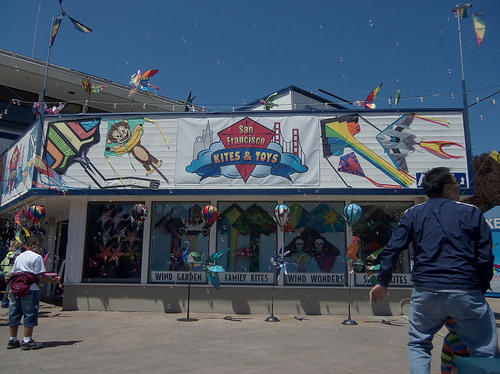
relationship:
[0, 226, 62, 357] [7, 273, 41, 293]
boy wearing fanny pack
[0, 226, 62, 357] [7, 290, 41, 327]
boy wearing jean shorts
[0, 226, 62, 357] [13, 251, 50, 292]
boy wearing shirt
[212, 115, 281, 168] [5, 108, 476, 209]
san francisco kites written on sign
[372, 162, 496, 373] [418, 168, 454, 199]
man has hair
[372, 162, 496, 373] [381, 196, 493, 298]
man wearing jacket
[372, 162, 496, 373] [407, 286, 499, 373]
man wearing jeans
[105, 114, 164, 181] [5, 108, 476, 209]
monkey on sign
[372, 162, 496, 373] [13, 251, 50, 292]
man wearing shirt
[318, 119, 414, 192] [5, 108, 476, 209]
kite on sign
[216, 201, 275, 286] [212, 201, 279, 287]
sign on window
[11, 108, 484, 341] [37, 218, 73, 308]
store has door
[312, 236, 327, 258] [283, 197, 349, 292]
skull on sign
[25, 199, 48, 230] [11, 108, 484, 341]
balls in front of store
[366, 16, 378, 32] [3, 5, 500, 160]
bubble in sky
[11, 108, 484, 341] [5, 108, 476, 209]
store has sign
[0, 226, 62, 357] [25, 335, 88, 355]
boy has shadow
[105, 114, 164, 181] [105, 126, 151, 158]
monkey has banana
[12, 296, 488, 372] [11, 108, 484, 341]
sidewalk in front of store